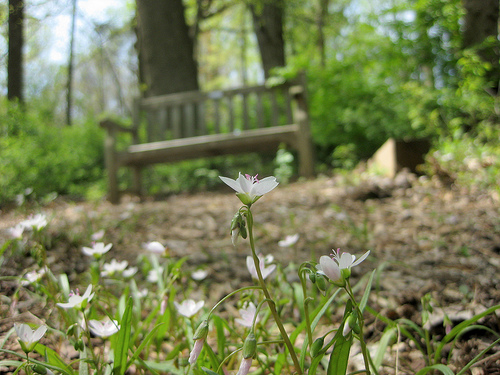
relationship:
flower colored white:
[219, 173, 304, 375] [240, 182, 255, 191]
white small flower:
[240, 182, 255, 191] [219, 173, 304, 375]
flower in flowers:
[219, 173, 304, 375] [2, 172, 372, 374]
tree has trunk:
[247, 2, 286, 81] [133, 2, 204, 136]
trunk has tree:
[133, 2, 204, 136] [247, 2, 286, 81]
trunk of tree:
[133, 2, 204, 136] [247, 2, 286, 81]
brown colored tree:
[143, 11, 182, 82] [133, 2, 204, 136]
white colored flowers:
[240, 182, 255, 191] [2, 172, 372, 374]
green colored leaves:
[16, 143, 53, 174] [2, 97, 109, 208]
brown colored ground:
[143, 11, 182, 82] [4, 185, 499, 315]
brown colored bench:
[143, 11, 182, 82] [97, 70, 312, 204]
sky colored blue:
[2, 2, 137, 123] [29, 2, 55, 18]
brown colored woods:
[143, 11, 182, 82] [1, 1, 498, 133]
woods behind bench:
[1, 1, 498, 133] [97, 70, 312, 204]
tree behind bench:
[247, 2, 286, 81] [97, 70, 312, 204]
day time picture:
[1, 1, 498, 133] [2, 0, 499, 374]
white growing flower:
[240, 182, 255, 191] [219, 173, 304, 375]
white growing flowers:
[240, 182, 255, 191] [2, 172, 372, 374]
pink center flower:
[243, 173, 250, 181] [219, 173, 304, 375]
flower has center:
[219, 173, 304, 375] [243, 173, 260, 185]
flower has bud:
[219, 173, 304, 375] [230, 213, 247, 248]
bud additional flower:
[230, 213, 247, 248] [219, 173, 304, 375]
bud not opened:
[230, 213, 247, 248] [82, 242, 115, 258]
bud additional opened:
[230, 213, 247, 248] [82, 242, 115, 258]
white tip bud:
[240, 182, 255, 191] [230, 213, 247, 248]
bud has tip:
[230, 213, 247, 248] [230, 226, 240, 251]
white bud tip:
[240, 182, 255, 191] [230, 226, 240, 251]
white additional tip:
[240, 182, 255, 191] [230, 226, 240, 251]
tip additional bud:
[230, 226, 240, 251] [230, 213, 247, 248]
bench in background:
[97, 70, 312, 204] [1, 1, 498, 133]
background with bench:
[1, 1, 498, 133] [97, 70, 312, 204]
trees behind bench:
[135, 2, 286, 143] [97, 70, 312, 204]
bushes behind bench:
[285, 11, 499, 162] [97, 70, 312, 204]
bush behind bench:
[2, 97, 109, 208] [97, 70, 312, 204]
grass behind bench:
[7, 148, 497, 217] [97, 70, 312, 204]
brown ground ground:
[143, 11, 182, 82] [4, 185, 499, 315]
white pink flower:
[240, 182, 255, 191] [219, 173, 304, 375]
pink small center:
[243, 173, 250, 181] [243, 173, 260, 185]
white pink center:
[240, 182, 255, 191] [243, 173, 260, 185]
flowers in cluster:
[2, 172, 372, 374] [13, 270, 130, 370]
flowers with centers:
[2, 172, 372, 374] [243, 172, 342, 266]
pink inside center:
[243, 173, 250, 181] [243, 173, 260, 185]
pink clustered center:
[243, 173, 250, 181] [243, 173, 260, 185]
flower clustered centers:
[219, 173, 304, 375] [243, 172, 342, 266]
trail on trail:
[4, 185, 499, 315] [2, 211, 497, 284]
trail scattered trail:
[4, 185, 499, 315] [2, 211, 497, 284]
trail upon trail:
[4, 185, 499, 315] [2, 211, 497, 284]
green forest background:
[16, 143, 53, 174] [1, 1, 498, 133]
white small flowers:
[240, 182, 255, 191] [2, 172, 372, 374]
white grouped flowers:
[240, 182, 255, 191] [2, 172, 372, 374]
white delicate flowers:
[240, 182, 255, 191] [2, 172, 372, 374]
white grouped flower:
[240, 182, 255, 191] [219, 173, 304, 375]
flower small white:
[219, 173, 304, 375] [240, 182, 255, 191]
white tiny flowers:
[240, 182, 255, 191] [2, 172, 372, 374]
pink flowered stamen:
[243, 173, 250, 181] [66, 289, 82, 303]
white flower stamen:
[240, 182, 255, 191] [66, 289, 82, 303]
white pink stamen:
[240, 182, 255, 191] [66, 289, 82, 303]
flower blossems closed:
[219, 173, 304, 375] [230, 213, 247, 248]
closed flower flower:
[230, 213, 247, 248] [219, 173, 304, 375]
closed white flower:
[230, 213, 247, 248] [219, 173, 304, 375]